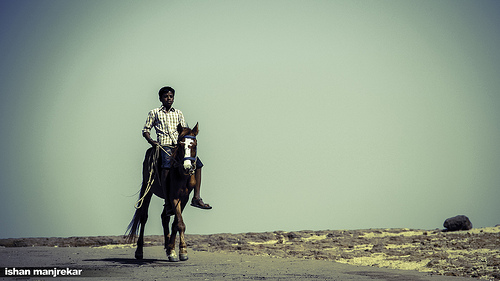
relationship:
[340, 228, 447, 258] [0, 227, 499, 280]
sand on beach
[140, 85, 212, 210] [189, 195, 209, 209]
boy wearing sandals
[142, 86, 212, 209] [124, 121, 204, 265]
boy riding horse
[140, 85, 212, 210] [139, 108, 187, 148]
boy wearing shirt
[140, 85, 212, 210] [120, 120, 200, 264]
boy on horse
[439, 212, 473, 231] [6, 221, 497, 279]
rock on road`s side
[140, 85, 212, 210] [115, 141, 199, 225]
boy on horse